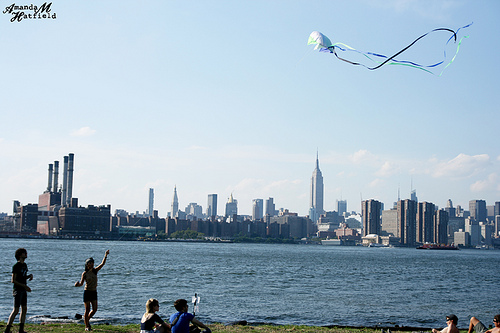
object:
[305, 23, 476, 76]
kite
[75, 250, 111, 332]
woman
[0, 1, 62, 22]
photographer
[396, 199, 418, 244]
buildings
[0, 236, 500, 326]
water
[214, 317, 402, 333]
grass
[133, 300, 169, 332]
people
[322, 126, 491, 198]
clouds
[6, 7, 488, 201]
sky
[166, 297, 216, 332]
man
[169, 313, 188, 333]
back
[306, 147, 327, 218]
building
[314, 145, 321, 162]
tip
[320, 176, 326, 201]
edge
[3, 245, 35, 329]
people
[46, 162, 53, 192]
smokestacks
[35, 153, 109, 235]
building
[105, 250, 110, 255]
hand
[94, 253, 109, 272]
arm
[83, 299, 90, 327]
legs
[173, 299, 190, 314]
head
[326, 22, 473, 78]
streamers